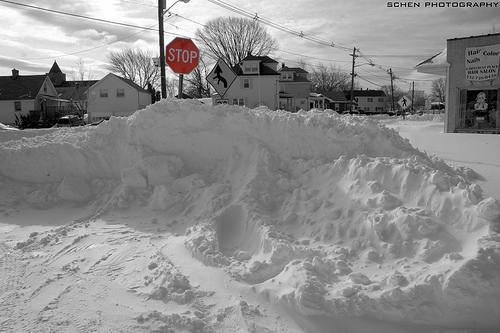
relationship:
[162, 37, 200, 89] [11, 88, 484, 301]
stop sign behind mound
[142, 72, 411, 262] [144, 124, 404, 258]
heap of sand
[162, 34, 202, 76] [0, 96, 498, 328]
sign beyond a snow bank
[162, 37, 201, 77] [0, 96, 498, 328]
stop sign behind a snow bank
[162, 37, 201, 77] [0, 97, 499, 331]
stop sign behind a snow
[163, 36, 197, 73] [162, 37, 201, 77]
top of a stop sign